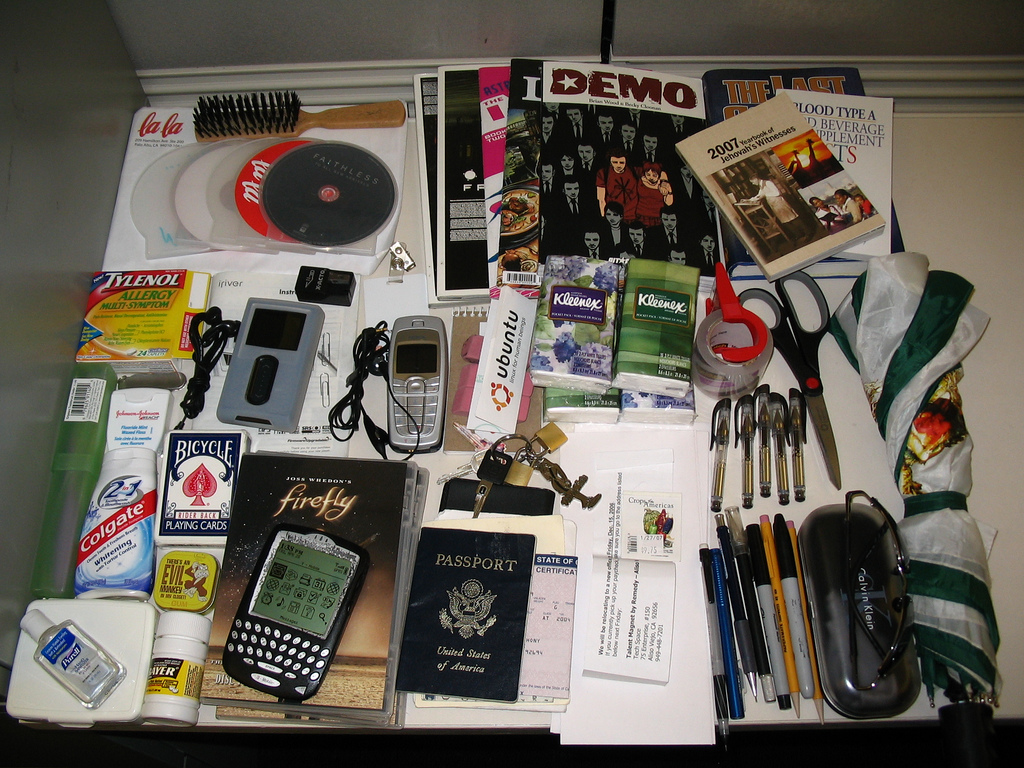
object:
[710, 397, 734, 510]
item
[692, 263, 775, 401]
item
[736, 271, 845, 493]
item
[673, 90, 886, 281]
item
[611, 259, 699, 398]
item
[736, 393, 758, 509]
item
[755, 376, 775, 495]
item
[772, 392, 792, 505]
item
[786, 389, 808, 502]
item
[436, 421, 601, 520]
item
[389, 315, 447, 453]
item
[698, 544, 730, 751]
item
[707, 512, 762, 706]
item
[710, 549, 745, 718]
item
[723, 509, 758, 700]
item